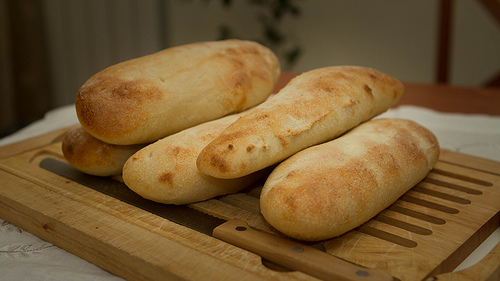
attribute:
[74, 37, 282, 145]
bread — piled, fresh baked, loaf, dark brown, cooling, baked, small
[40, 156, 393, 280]
knife — sawtoothed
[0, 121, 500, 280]
cutting board — wooden, brown, slitted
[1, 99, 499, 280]
table cloth — patterned, white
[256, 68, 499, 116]
table — wooden, brown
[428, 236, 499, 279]
handle — wooden, brown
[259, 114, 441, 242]
bread — piled, loaf, fresh baked, baked, small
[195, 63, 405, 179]
bread — piled, fresh baked, loaf, baked, small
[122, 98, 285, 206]
bread — loaf, piled, fresh baked, baked, small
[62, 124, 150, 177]
bread — piled, fresh baked, loaf, baked, small, light brown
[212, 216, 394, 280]
handle — wooden, brown, wood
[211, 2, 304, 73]
plant — distant